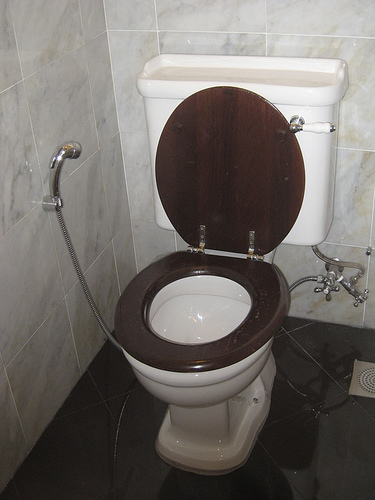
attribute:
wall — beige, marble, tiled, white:
[0, 2, 374, 491]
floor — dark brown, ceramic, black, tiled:
[1, 316, 374, 498]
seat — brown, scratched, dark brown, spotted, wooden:
[114, 251, 291, 372]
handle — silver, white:
[288, 116, 335, 135]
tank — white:
[137, 53, 347, 247]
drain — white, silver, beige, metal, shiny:
[349, 358, 374, 399]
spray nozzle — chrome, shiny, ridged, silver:
[49, 143, 85, 195]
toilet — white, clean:
[121, 338, 279, 477]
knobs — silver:
[315, 261, 369, 309]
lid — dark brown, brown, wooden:
[156, 85, 306, 254]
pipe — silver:
[289, 270, 324, 291]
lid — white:
[138, 52, 350, 108]